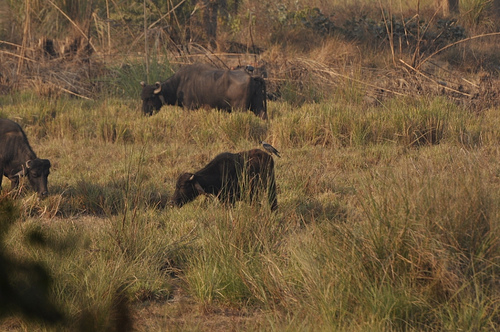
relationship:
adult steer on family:
[167, 142, 281, 211] [0, 55, 265, 197]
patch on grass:
[320, 140, 485, 222] [290, 135, 492, 326]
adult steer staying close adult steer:
[167, 142, 281, 211] [0, 111, 52, 199]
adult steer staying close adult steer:
[0, 111, 52, 199] [167, 142, 281, 211]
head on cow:
[121, 64, 174, 126] [127, 64, 276, 129]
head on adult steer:
[164, 157, 206, 222] [167, 142, 281, 211]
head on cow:
[23, 149, 61, 206] [143, 124, 332, 228]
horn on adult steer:
[151, 75, 166, 105] [139, 61, 268, 118]